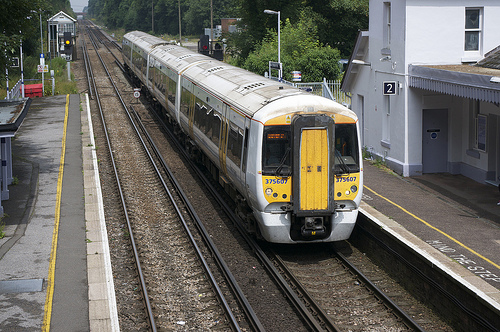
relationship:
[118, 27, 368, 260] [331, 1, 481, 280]
incoming train at a train station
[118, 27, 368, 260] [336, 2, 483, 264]
incoming train at a train station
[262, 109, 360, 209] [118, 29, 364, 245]
front on incoming train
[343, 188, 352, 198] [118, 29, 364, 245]
headlight on incoming train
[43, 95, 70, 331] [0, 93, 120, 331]
line on platform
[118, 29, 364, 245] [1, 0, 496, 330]
incoming train at station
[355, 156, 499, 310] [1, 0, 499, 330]
platform at train station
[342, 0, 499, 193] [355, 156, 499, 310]
building on platform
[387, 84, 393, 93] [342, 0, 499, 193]
number 2 on building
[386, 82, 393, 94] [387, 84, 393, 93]
number 2 on number 2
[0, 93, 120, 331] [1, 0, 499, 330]
platform at train station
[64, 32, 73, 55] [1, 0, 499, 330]
train signal at train station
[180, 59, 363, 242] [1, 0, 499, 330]
train car at train station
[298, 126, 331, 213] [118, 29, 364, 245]
door on incoming train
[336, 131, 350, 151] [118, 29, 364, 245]
driver in incoming train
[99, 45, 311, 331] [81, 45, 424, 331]
gravel between tracks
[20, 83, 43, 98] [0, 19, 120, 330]
object on ground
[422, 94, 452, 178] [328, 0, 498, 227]
door on building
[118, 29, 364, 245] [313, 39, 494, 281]
incoming train at station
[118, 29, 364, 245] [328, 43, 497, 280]
incoming train at station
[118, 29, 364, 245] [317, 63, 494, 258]
incoming train at station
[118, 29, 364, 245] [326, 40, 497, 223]
incoming train at station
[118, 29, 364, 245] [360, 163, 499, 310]
incoming train at platform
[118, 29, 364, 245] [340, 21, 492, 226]
incoming train at station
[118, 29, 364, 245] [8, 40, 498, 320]
incoming train at train station